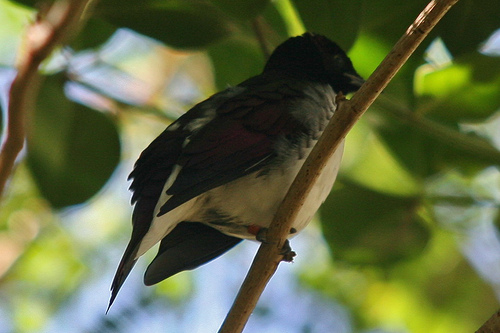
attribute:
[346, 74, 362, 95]
beak — gray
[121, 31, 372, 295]
bird — small, black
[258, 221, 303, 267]
legs — black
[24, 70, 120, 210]
leaf — Green 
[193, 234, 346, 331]
sky — blue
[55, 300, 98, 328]
sky — blue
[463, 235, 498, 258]
sky — blue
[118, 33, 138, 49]
sky — blue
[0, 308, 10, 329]
sky — blue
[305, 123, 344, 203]
white chest — white 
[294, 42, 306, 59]
feathers — black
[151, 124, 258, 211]
feathers — white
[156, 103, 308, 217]
wing — black, red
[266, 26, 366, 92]
head — black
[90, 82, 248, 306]
wing — black, tinge of red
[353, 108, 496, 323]
leaves — green, out of focus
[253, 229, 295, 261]
feet — black 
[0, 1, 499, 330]
leaves — green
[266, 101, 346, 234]
breast — white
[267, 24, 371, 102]
head — black 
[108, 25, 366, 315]
bird — Black 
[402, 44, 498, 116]
leaf — green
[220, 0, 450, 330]
branch — bare